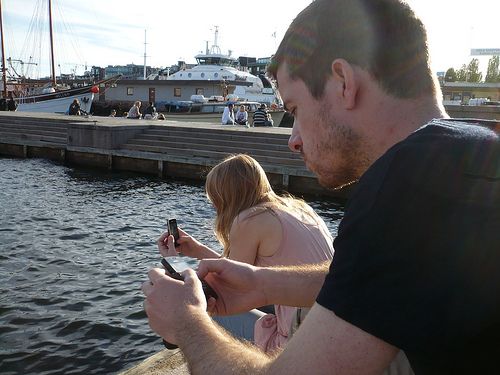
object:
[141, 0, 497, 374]
man woman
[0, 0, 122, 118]
boat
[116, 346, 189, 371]
dock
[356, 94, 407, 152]
ground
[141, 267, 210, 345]
hand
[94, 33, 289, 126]
boat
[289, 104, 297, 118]
eye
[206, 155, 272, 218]
head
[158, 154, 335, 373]
lady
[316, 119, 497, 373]
sweater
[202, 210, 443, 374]
arm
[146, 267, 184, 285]
fingers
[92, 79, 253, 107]
building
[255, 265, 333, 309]
arm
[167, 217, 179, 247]
cell phone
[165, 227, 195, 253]
hand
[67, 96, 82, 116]
man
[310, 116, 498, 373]
t-shirt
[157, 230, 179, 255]
hand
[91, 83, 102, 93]
ball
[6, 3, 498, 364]
air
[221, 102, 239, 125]
lady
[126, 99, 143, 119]
lady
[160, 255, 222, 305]
cell phone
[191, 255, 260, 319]
man's hand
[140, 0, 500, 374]
guy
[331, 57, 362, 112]
ear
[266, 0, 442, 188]
head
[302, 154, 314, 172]
mouth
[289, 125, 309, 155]
nose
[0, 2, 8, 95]
mast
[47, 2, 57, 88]
mast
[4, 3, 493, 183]
marina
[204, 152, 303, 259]
hair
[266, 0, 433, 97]
hair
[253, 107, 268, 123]
sweater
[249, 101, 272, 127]
person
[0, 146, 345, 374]
water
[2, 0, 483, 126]
distance